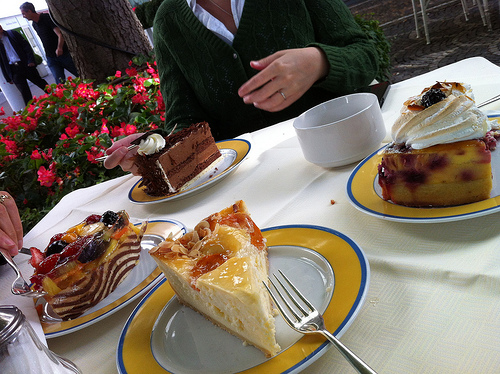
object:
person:
[129, 0, 393, 146]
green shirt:
[129, 0, 395, 147]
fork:
[256, 268, 380, 373]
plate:
[116, 222, 373, 374]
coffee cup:
[292, 92, 386, 170]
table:
[0, 55, 500, 373]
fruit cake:
[376, 81, 499, 213]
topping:
[391, 81, 493, 151]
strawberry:
[27, 245, 62, 275]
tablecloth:
[0, 57, 500, 374]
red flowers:
[2, 57, 171, 204]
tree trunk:
[45, 0, 157, 84]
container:
[0, 303, 86, 373]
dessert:
[28, 210, 147, 322]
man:
[17, 2, 79, 87]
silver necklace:
[198, 0, 246, 17]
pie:
[128, 121, 226, 198]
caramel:
[170, 140, 192, 158]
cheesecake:
[146, 199, 282, 358]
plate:
[344, 112, 499, 223]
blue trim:
[343, 170, 359, 199]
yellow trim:
[359, 176, 373, 194]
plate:
[125, 138, 252, 205]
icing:
[136, 131, 161, 156]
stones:
[395, 28, 454, 60]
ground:
[393, 0, 499, 87]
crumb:
[327, 199, 337, 206]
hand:
[0, 188, 26, 257]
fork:
[0, 247, 48, 298]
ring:
[0, 193, 10, 205]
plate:
[22, 217, 187, 338]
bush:
[0, 46, 165, 236]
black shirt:
[30, 13, 68, 61]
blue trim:
[324, 222, 363, 262]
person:
[0, 24, 52, 107]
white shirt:
[0, 34, 20, 64]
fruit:
[28, 210, 126, 279]